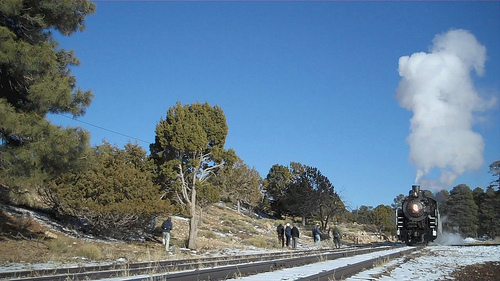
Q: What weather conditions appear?
A: It is cloudless.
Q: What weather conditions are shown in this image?
A: It is cloudless.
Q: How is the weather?
A: It is cloudless.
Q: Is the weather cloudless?
A: Yes, it is cloudless.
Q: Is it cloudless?
A: Yes, it is cloudless.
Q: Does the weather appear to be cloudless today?
A: Yes, it is cloudless.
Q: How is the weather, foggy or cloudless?
A: It is cloudless.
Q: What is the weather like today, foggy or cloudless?
A: It is cloudless.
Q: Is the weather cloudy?
A: No, it is cloudless.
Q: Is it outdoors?
A: Yes, it is outdoors.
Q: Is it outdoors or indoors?
A: It is outdoors.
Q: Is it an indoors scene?
A: No, it is outdoors.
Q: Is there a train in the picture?
A: Yes, there is a train.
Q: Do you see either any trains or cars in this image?
A: Yes, there is a train.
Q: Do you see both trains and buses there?
A: No, there is a train but no buses.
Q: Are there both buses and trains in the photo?
A: No, there is a train but no buses.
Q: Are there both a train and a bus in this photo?
A: No, there is a train but no buses.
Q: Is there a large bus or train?
A: Yes, there is a large train.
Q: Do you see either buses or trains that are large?
A: Yes, the train is large.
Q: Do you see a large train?
A: Yes, there is a large train.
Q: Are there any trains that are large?
A: Yes, there is a train that is large.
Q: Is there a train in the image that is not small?
A: Yes, there is a large train.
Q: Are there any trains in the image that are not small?
A: Yes, there is a large train.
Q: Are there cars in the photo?
A: No, there are no cars.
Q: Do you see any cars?
A: No, there are no cars.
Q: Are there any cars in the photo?
A: No, there are no cars.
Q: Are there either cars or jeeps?
A: No, there are no cars or jeeps.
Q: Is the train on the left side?
A: No, the train is on the right of the image.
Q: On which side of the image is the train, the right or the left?
A: The train is on the right of the image.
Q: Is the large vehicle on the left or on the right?
A: The train is on the right of the image.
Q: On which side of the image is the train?
A: The train is on the right of the image.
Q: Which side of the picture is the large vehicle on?
A: The train is on the right of the image.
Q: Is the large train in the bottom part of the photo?
A: Yes, the train is in the bottom of the image.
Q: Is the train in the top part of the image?
A: No, the train is in the bottom of the image.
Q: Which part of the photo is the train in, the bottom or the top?
A: The train is in the bottom of the image.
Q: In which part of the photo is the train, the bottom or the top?
A: The train is in the bottom of the image.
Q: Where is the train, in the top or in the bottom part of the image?
A: The train is in the bottom of the image.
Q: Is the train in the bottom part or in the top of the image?
A: The train is in the bottom of the image.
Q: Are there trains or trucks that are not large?
A: No, there is a train but it is large.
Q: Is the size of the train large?
A: Yes, the train is large.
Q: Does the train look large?
A: Yes, the train is large.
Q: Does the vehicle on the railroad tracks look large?
A: Yes, the train is large.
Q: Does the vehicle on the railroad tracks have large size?
A: Yes, the train is large.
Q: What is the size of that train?
A: The train is large.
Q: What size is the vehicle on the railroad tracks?
A: The train is large.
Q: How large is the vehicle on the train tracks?
A: The train is large.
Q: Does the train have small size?
A: No, the train is large.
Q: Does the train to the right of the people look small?
A: No, the train is large.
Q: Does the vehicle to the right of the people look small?
A: No, the train is large.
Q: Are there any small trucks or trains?
A: No, there is a train but it is large.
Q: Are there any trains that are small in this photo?
A: No, there is a train but it is large.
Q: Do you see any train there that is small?
A: No, there is a train but it is large.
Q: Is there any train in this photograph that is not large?
A: No, there is a train but it is large.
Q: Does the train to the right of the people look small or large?
A: The train is large.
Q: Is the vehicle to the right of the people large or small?
A: The train is large.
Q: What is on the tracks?
A: The train is on the tracks.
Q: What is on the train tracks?
A: The train is on the tracks.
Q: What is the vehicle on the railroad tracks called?
A: The vehicle is a train.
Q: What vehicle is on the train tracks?
A: The vehicle is a train.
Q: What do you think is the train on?
A: The train is on the tracks.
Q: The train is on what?
A: The train is on the tracks.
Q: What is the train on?
A: The train is on the tracks.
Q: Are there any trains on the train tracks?
A: Yes, there is a train on the train tracks.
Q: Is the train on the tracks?
A: Yes, the train is on the tracks.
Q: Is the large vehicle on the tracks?
A: Yes, the train is on the tracks.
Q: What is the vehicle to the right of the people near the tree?
A: The vehicle is a train.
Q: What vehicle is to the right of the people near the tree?
A: The vehicle is a train.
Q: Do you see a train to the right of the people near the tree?
A: Yes, there is a train to the right of the people.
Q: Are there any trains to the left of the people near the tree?
A: No, the train is to the right of the people.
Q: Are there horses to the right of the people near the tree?
A: No, there is a train to the right of the people.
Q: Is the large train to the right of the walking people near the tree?
A: Yes, the train is to the right of the people.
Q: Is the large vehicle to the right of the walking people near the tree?
A: Yes, the train is to the right of the people.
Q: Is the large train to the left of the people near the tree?
A: No, the train is to the right of the people.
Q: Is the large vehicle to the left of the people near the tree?
A: No, the train is to the right of the people.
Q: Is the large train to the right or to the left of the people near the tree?
A: The train is to the right of the people.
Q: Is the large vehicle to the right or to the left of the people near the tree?
A: The train is to the right of the people.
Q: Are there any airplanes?
A: No, there are no airplanes.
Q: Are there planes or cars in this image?
A: No, there are no planes or cars.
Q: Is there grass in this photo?
A: Yes, there is grass.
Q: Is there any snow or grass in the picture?
A: Yes, there is grass.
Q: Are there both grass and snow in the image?
A: Yes, there are both grass and snow.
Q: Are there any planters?
A: No, there are no planters.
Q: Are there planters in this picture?
A: No, there are no planters.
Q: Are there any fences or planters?
A: No, there are no planters or fences.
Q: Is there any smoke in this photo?
A: Yes, there is smoke.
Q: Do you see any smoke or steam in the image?
A: Yes, there is smoke.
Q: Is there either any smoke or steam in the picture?
A: Yes, there is smoke.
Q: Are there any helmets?
A: No, there are no helmets.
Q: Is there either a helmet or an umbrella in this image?
A: No, there are no helmets or umbrellas.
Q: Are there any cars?
A: No, there are no cars.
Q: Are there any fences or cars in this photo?
A: No, there are no cars or fences.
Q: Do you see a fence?
A: No, there are no fences.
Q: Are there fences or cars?
A: No, there are no fences or cars.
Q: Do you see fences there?
A: No, there are no fences.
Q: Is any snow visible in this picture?
A: Yes, there is snow.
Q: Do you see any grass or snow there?
A: Yes, there is snow.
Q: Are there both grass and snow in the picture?
A: Yes, there are both snow and grass.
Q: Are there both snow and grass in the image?
A: Yes, there are both snow and grass.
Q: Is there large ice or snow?
A: Yes, there is large snow.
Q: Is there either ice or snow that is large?
A: Yes, the snow is large.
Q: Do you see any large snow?
A: Yes, there is large snow.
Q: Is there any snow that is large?
A: Yes, there is snow that is large.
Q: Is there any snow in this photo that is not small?
A: Yes, there is large snow.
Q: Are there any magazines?
A: No, there are no magazines.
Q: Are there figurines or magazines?
A: No, there are no magazines or figurines.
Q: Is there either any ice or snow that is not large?
A: No, there is snow but it is large.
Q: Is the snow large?
A: Yes, the snow is large.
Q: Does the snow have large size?
A: Yes, the snow is large.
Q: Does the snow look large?
A: Yes, the snow is large.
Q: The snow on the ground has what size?
A: The snow is large.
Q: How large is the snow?
A: The snow is large.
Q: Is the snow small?
A: No, the snow is large.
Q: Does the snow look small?
A: No, the snow is large.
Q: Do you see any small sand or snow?
A: No, there is snow but it is large.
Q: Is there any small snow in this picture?
A: No, there is snow but it is large.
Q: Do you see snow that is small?
A: No, there is snow but it is large.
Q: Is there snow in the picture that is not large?
A: No, there is snow but it is large.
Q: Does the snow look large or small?
A: The snow is large.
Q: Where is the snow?
A: The snow is on the ground.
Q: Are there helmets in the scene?
A: No, there are no helmets.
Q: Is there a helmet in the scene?
A: No, there are no helmets.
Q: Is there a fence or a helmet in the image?
A: No, there are no helmets or fences.